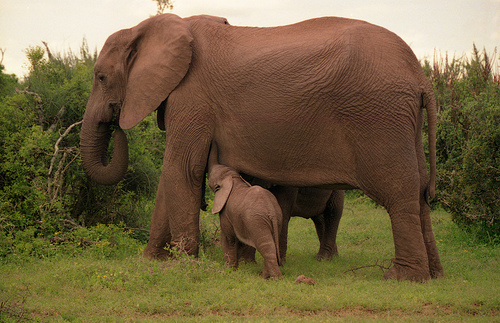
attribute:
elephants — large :
[74, 7, 449, 284]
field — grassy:
[78, 227, 148, 286]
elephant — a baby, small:
[206, 139, 281, 281]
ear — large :
[114, 12, 194, 132]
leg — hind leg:
[369, 75, 451, 281]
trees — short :
[12, 143, 79, 248]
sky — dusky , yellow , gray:
[0, 0, 498, 85]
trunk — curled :
[71, 96, 130, 186]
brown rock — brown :
[290, 270, 319, 288]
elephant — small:
[265, 175, 344, 261]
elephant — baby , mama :
[205, 137, 287, 279]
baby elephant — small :
[172, 162, 307, 256]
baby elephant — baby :
[206, 138, 284, 278]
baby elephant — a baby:
[202, 159, 289, 284]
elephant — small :
[201, 141, 291, 281]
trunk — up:
[205, 142, 217, 171]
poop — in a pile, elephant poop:
[289, 273, 319, 289]